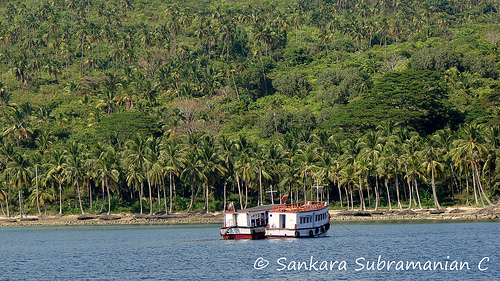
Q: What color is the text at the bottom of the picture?
A: White.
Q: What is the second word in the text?
A: Subramanian.